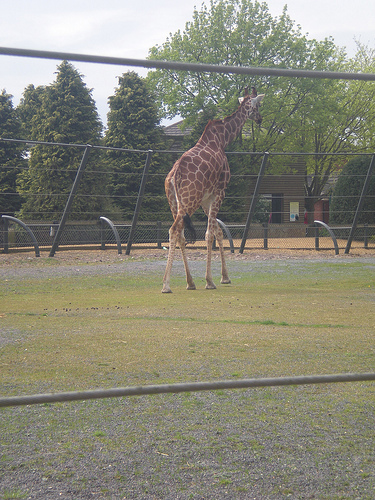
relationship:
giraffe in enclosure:
[157, 88, 265, 291] [7, 134, 372, 496]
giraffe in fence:
[157, 88, 265, 291] [32, 133, 358, 263]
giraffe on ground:
[157, 88, 265, 291] [53, 260, 309, 382]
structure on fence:
[16, 210, 361, 251] [32, 133, 358, 263]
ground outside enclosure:
[234, 220, 332, 247] [30, 92, 368, 392]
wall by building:
[310, 208, 355, 239] [193, 159, 317, 224]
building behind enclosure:
[206, 151, 351, 233] [73, 68, 370, 359]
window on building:
[257, 196, 282, 217] [125, 150, 343, 231]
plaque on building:
[282, 195, 307, 221] [151, 151, 359, 268]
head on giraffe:
[237, 86, 264, 126] [156, 90, 282, 252]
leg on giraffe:
[205, 205, 214, 270] [142, 94, 360, 318]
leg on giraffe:
[205, 205, 214, 270] [156, 92, 295, 294]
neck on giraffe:
[191, 98, 246, 147] [132, 85, 328, 319]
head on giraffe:
[232, 98, 271, 138] [123, 98, 309, 265]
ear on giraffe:
[239, 85, 267, 108] [164, 109, 272, 264]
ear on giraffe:
[239, 90, 253, 100] [177, 92, 350, 314]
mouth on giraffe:
[251, 111, 276, 130] [154, 86, 305, 285]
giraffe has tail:
[157, 88, 265, 291] [172, 164, 196, 244]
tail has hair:
[169, 179, 202, 250] [184, 214, 194, 244]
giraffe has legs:
[157, 88, 265, 291] [167, 208, 229, 295]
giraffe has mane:
[157, 88, 265, 291] [193, 97, 248, 140]